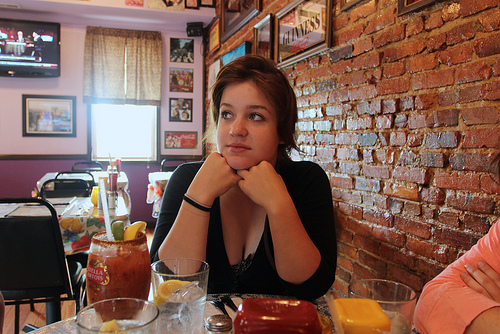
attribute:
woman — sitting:
[148, 56, 336, 301]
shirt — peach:
[409, 214, 499, 333]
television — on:
[0, 17, 62, 79]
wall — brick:
[204, 1, 498, 308]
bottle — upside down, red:
[236, 293, 322, 333]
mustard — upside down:
[331, 297, 390, 333]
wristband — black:
[183, 193, 212, 215]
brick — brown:
[409, 68, 455, 91]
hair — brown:
[209, 53, 301, 161]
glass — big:
[87, 226, 152, 325]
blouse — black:
[151, 159, 338, 304]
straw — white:
[98, 178, 114, 241]